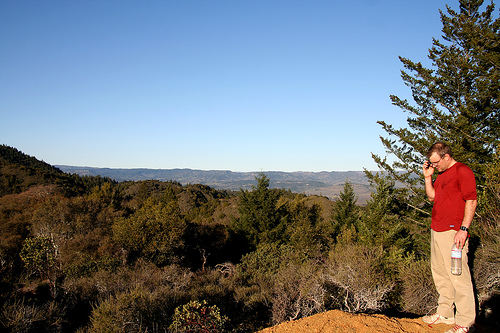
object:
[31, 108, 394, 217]
landscape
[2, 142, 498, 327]
landscape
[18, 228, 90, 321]
trees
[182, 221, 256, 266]
shadow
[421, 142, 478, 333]
man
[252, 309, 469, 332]
hill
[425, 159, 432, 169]
cellphone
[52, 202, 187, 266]
trees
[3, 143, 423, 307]
hill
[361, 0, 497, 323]
pine tree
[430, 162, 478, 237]
t-shirt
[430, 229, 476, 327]
pants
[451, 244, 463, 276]
water bottle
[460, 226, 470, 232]
watch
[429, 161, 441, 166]
glasses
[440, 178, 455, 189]
logo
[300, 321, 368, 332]
soil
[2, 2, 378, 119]
sky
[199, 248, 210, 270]
branches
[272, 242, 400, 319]
bushes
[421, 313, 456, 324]
shoes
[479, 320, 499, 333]
shade